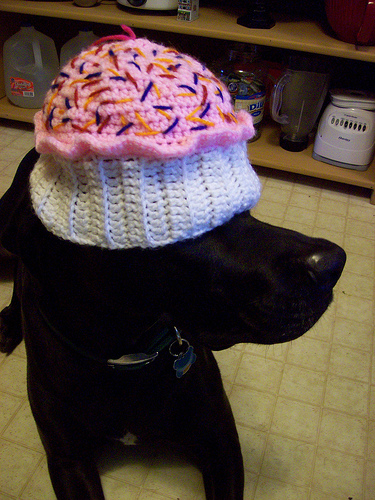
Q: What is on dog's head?
A: Hat.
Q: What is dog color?
A: Black.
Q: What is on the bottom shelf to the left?
A: Two gallons of water.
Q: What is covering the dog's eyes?
A: A crocheted hat.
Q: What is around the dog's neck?
A: A collar.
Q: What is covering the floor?
A: Linoleum.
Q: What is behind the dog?
A: Wooden shelves.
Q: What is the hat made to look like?
A: A cup cake.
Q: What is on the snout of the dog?
A: A black wet nose.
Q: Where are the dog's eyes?
A: Under the hat.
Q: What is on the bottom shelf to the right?
A: A blender base.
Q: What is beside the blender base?
A: A blender pitcher.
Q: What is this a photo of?
A: Black dog wearing beanie.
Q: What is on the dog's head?
A: Pink and white knitted beanie.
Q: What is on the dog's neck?
A: A collar.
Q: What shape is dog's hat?
A: Cupcake shape.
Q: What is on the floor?
A: Tile.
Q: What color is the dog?
A: Black.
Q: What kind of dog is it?
A: A Labrador.